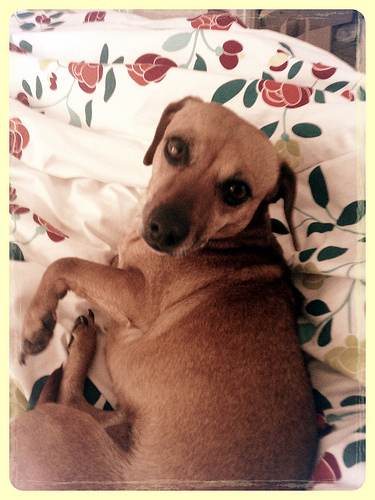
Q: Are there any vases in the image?
A: No, there are no vases.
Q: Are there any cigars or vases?
A: No, there are no vases or cigars.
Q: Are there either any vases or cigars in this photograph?
A: No, there are no vases or cigars.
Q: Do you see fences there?
A: No, there are no fences.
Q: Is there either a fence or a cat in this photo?
A: No, there are no fences or cats.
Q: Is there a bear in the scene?
A: No, there are no bears.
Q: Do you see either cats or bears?
A: No, there are no bears or cats.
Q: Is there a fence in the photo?
A: No, there are no fences.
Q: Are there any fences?
A: No, there are no fences.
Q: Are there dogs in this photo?
A: Yes, there is a dog.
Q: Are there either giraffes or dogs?
A: Yes, there is a dog.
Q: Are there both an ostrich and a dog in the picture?
A: No, there is a dog but no ostriches.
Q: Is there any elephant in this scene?
A: No, there are no elephants.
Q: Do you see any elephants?
A: No, there are no elephants.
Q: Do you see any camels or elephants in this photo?
A: No, there are no elephants or camels.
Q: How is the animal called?
A: The animal is a dog.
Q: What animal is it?
A: The animal is a dog.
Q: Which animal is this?
A: This is a dog.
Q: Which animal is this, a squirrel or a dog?
A: This is a dog.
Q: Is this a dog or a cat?
A: This is a dog.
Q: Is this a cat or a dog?
A: This is a dog.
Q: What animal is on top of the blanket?
A: The dog is on top of the blanket.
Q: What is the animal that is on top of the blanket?
A: The animal is a dog.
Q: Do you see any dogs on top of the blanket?
A: Yes, there is a dog on top of the blanket.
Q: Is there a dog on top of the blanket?
A: Yes, there is a dog on top of the blanket.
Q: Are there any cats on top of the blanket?
A: No, there is a dog on top of the blanket.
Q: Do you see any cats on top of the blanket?
A: No, there is a dog on top of the blanket.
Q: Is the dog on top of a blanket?
A: Yes, the dog is on top of a blanket.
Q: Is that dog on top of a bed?
A: No, the dog is on top of a blanket.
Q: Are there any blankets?
A: Yes, there is a blanket.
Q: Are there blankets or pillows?
A: Yes, there is a blanket.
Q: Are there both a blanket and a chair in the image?
A: No, there is a blanket but no chairs.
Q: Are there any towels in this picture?
A: No, there are no towels.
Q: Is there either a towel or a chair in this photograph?
A: No, there are no towels or chairs.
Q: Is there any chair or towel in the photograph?
A: No, there are no towels or chairs.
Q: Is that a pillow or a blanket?
A: That is a blanket.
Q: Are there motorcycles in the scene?
A: No, there are no motorcycles.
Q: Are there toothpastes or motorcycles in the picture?
A: No, there are no motorcycles or toothpastes.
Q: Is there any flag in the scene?
A: No, there are no flags.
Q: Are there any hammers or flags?
A: No, there are no flags or hammers.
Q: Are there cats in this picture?
A: No, there are no cats.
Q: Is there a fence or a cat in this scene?
A: No, there are no cats or fences.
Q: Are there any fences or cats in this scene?
A: No, there are no cats or fences.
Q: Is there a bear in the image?
A: No, there are no bears.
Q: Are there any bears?
A: No, there are no bears.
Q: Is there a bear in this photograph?
A: No, there are no bears.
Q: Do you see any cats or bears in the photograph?
A: No, there are no bears or cats.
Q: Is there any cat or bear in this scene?
A: No, there are no bears or cats.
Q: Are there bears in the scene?
A: No, there are no bears.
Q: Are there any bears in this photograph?
A: No, there are no bears.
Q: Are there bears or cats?
A: No, there are no bears or cats.